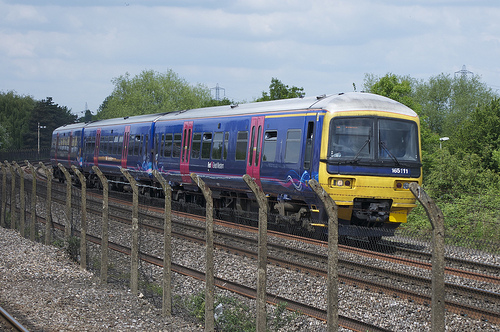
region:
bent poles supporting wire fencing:
[12, 150, 454, 317]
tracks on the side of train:
[55, 192, 367, 322]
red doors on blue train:
[87, 100, 282, 190]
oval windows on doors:
[225, 116, 272, 186]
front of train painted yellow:
[310, 95, 427, 230]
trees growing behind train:
[65, 50, 465, 215]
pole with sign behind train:
[30, 115, 45, 156]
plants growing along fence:
[26, 210, 293, 325]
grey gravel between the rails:
[45, 216, 315, 321]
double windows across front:
[330, 116, 417, 167]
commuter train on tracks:
[8, 34, 457, 269]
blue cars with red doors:
[49, 120, 319, 185]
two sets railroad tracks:
[6, 148, 478, 270]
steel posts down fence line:
[8, 154, 428, 316]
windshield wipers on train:
[351, 128, 420, 170]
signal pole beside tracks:
[27, 111, 55, 163]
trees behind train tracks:
[396, 76, 499, 247]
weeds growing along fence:
[56, 231, 243, 326]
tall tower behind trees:
[204, 73, 231, 105]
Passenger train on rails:
[34, 85, 436, 236]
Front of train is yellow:
[316, 96, 427, 233]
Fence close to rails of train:
[9, 154, 485, 330]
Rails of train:
[176, 228, 498, 328]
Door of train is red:
[236, 114, 268, 193]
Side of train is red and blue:
[56, 116, 322, 195]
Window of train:
[257, 124, 308, 170]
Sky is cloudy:
[0, 0, 492, 80]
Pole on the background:
[34, 105, 56, 162]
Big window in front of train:
[323, 111, 427, 181]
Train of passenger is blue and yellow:
[37, 82, 433, 252]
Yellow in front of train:
[313, 100, 430, 232]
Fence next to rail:
[6, 157, 489, 329]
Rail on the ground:
[80, 224, 495, 329]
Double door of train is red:
[235, 111, 274, 196]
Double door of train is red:
[170, 111, 202, 181]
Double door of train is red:
[115, 114, 136, 171]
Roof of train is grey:
[48, 81, 423, 119]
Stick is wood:
[301, 171, 356, 330]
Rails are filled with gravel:
[112, 224, 484, 328]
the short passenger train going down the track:
[48, 109, 429, 220]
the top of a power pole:
[203, 82, 228, 104]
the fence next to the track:
[4, 160, 496, 330]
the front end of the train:
[320, 93, 421, 226]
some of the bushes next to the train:
[416, 73, 499, 247]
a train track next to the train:
[33, 175, 499, 330]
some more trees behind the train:
[2, 92, 66, 159]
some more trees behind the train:
[97, 75, 208, 115]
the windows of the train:
[153, 115, 326, 185]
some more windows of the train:
[49, 130, 150, 167]